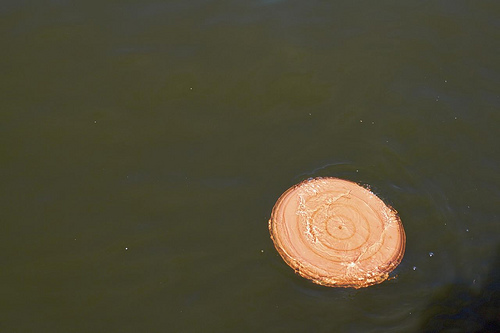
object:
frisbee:
[267, 176, 405, 289]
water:
[0, 0, 499, 332]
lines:
[320, 213, 358, 240]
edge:
[263, 213, 340, 290]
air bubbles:
[424, 251, 435, 260]